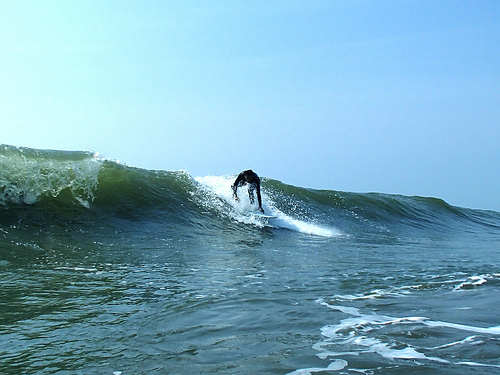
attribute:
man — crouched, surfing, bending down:
[232, 169, 265, 214]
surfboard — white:
[247, 206, 276, 219]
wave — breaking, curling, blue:
[1, 142, 500, 239]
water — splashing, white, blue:
[0, 142, 499, 375]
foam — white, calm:
[288, 273, 500, 375]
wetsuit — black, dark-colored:
[232, 170, 264, 206]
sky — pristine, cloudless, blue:
[0, 0, 499, 214]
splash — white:
[199, 174, 349, 239]